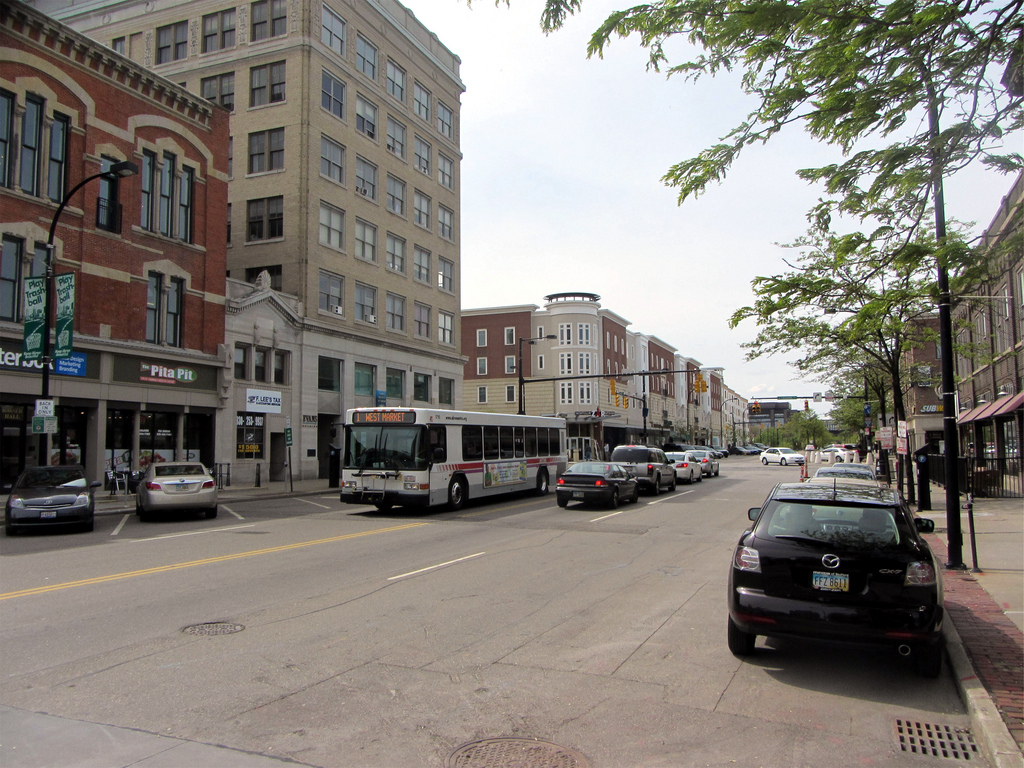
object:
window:
[142, 150, 192, 245]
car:
[728, 481, 949, 682]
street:
[0, 445, 988, 768]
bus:
[339, 406, 567, 510]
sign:
[140, 364, 198, 382]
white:
[446, 424, 463, 462]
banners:
[22, 272, 76, 361]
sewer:
[885, 715, 984, 760]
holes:
[184, 620, 244, 638]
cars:
[555, 445, 722, 516]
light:
[692, 372, 708, 393]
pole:
[35, 170, 106, 465]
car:
[139, 462, 222, 523]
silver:
[172, 496, 197, 501]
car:
[0, 468, 95, 537]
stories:
[0, 0, 230, 501]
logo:
[821, 552, 840, 569]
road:
[2, 450, 988, 768]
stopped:
[556, 462, 639, 508]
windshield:
[347, 427, 426, 470]